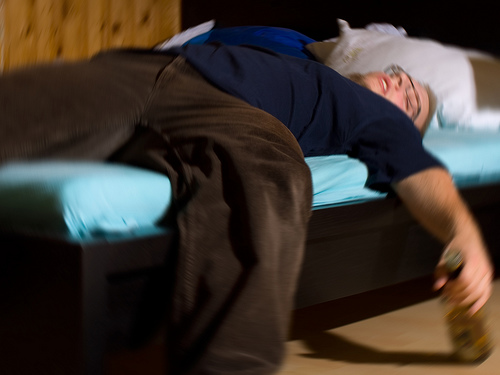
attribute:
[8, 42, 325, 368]
pants — brown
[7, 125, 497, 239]
sheet — blue, bed's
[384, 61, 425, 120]
eyeglasses — black framed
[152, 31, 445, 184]
shirt — blue, short sleeve, man's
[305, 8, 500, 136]
pillow — white, plump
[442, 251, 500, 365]
bottle — liquor filled, beer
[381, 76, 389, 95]
teeth — white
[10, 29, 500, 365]
man — laying, laying back, sleeping, young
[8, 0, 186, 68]
wall — wood, paneled, light, wooden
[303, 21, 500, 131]
case — white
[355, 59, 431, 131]
face — man's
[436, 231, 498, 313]
hand — man's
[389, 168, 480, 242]
arm — tanned, man's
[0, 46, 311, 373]
jeans — denim, brown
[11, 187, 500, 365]
frame — wooden, dark, bed's, brown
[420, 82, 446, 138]
hair — blond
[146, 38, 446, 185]
t-shirt — dark blue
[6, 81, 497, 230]
bed sheet — blue